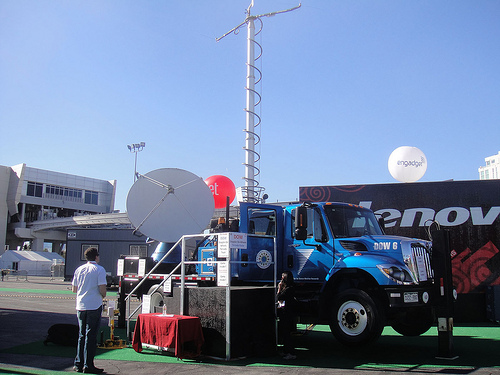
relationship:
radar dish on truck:
[125, 168, 212, 260] [115, 200, 437, 345]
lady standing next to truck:
[53, 246, 119, 373] [167, 194, 433, 352]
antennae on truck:
[207, 15, 312, 205] [217, 201, 426, 348]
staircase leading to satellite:
[121, 230, 279, 364] [125, 165, 216, 242]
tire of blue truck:
[332, 291, 389, 353] [118, 203, 437, 347]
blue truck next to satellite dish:
[118, 203, 437, 347] [113, 158, 233, 253]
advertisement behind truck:
[368, 201, 498, 228] [94, 193, 464, 363]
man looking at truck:
[55, 233, 120, 374] [141, 201, 459, 348]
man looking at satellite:
[55, 233, 120, 374] [116, 139, 223, 259]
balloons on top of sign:
[387, 144, 427, 183] [296, 182, 498, 316]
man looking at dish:
[67, 245, 109, 374] [125, 168, 215, 237]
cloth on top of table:
[132, 309, 209, 367] [130, 309, 209, 364]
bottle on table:
[162, 302, 167, 317] [135, 313, 198, 359]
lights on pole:
[124, 136, 144, 181] [103, 131, 160, 189]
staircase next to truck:
[121, 230, 279, 364] [95, 162, 436, 352]